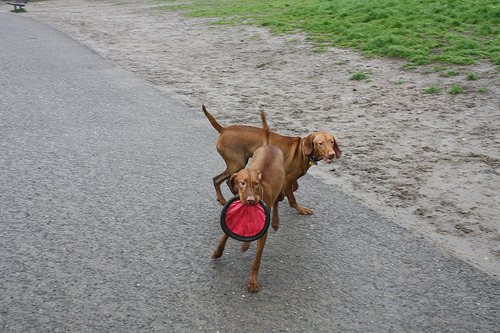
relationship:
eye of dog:
[314, 138, 324, 148] [211, 146, 302, 282]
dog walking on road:
[200, 102, 343, 218] [2, 9, 495, 327]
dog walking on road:
[214, 108, 289, 292] [2, 9, 495, 327]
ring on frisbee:
[218, 193, 271, 244] [181, 160, 294, 241]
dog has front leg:
[211, 108, 289, 292] [249, 213, 276, 293]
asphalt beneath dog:
[0, 12, 499, 331] [200, 102, 343, 218]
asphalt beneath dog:
[0, 12, 499, 331] [211, 108, 289, 292]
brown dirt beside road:
[28, 2, 498, 284] [2, 9, 495, 327]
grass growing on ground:
[270, 5, 489, 74] [2, 2, 498, 281]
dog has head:
[200, 102, 343, 218] [303, 127, 347, 165]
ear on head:
[298, 133, 316, 158] [303, 127, 347, 165]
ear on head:
[332, 135, 344, 162] [303, 127, 347, 165]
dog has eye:
[214, 108, 289, 292] [237, 180, 247, 187]